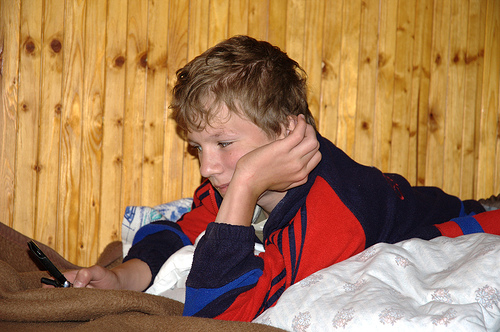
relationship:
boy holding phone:
[178, 63, 357, 229] [18, 236, 70, 288]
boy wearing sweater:
[178, 63, 357, 229] [311, 163, 422, 232]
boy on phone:
[178, 63, 357, 229] [18, 236, 70, 288]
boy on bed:
[178, 63, 357, 229] [352, 236, 499, 315]